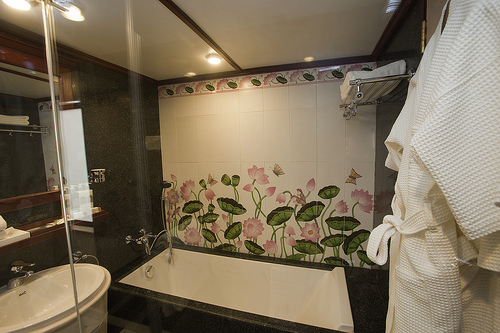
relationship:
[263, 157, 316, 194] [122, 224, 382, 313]
butterfly by bathtub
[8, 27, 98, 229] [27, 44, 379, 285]
mirror in bathroom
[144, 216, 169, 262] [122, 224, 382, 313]
spout of bathtub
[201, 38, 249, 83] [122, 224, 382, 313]
light over bathtub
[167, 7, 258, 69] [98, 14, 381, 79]
line on ceiling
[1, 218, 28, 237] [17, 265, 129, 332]
dish above sink